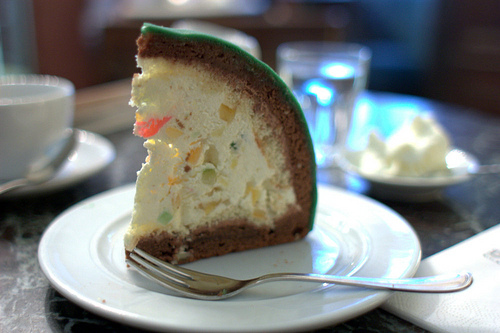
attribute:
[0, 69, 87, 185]
cup — white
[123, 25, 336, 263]
cake — sliced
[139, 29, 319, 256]
cake — chocolate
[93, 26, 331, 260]
cake — green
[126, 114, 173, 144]
fruit — pink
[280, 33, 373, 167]
glass — blurry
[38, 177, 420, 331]
plate — round, white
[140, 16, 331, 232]
icing — green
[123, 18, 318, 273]
cake — yellow, sliced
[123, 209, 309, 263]
layer — brown